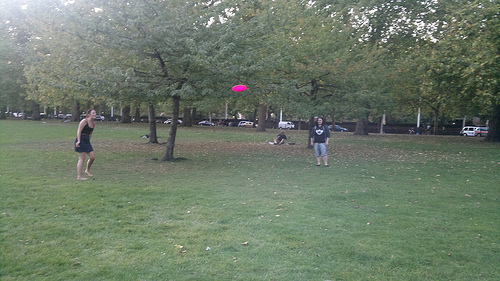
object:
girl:
[71, 107, 101, 180]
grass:
[0, 120, 500, 278]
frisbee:
[231, 83, 249, 93]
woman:
[307, 115, 331, 167]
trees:
[0, 1, 496, 151]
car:
[326, 124, 348, 133]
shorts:
[312, 143, 327, 156]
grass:
[0, 174, 481, 271]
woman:
[74, 105, 99, 181]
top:
[80, 112, 95, 141]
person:
[268, 129, 292, 144]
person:
[270, 128, 285, 145]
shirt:
[73, 116, 97, 141]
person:
[74, 103, 96, 183]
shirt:
[309, 123, 329, 143]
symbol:
[313, 127, 321, 136]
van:
[279, 121, 294, 129]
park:
[0, 0, 497, 274]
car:
[198, 119, 215, 125]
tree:
[0, 0, 296, 159]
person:
[309, 116, 330, 166]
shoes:
[315, 158, 328, 169]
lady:
[308, 114, 330, 167]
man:
[75, 110, 97, 184]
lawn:
[0, 136, 497, 278]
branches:
[150, 40, 193, 96]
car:
[459, 124, 490, 136]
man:
[309, 115, 332, 165]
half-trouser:
[312, 142, 330, 159]